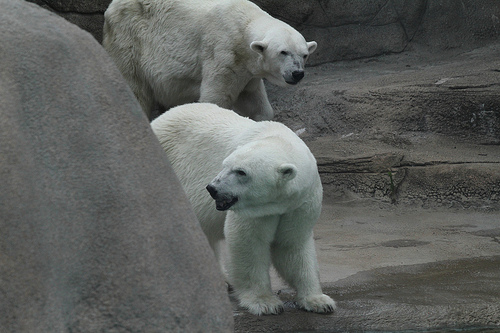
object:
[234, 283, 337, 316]
claws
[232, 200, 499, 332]
ground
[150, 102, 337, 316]
bear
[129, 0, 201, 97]
fur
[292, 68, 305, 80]
nose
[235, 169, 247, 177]
eyes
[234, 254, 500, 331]
water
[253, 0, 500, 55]
wall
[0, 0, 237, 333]
rock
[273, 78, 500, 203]
ledges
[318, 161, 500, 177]
crevices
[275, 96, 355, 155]
stone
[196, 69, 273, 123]
legs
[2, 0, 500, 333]
zoo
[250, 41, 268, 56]
ears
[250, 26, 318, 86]
head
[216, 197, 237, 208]
teeth